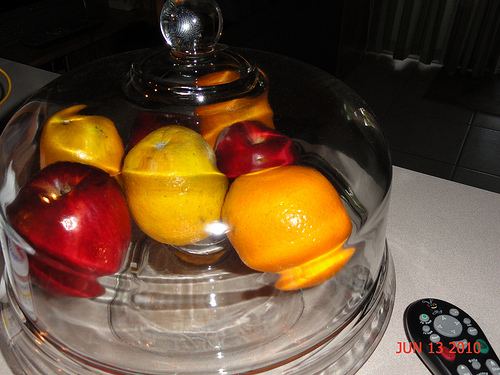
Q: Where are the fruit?
A: In a glass container.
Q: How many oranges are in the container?
A: Four.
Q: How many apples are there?
A: Two.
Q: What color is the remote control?
A: Black.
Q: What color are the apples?
A: Red.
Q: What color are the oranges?
A: Orange.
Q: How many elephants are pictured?
A: Zero.